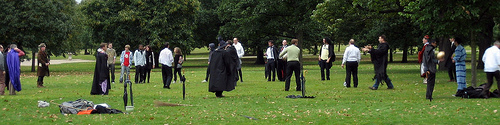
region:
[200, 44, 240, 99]
a person wearing a black cape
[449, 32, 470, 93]
a person wearing a blue strip jumpsuit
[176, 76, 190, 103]
an umbrellas stuck into th ground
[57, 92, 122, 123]
a pile of clothes on the grass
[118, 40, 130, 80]
a young man wearing a red t-shirt and gray jacket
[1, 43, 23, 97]
a person adjusting a blue cape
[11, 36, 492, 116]
people playing a mysterious game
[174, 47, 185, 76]
a girl carrying a bag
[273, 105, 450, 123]
brown leaves scattered on the ground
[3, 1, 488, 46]
trees surrounding the area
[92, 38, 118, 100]
person in long garmet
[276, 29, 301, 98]
man starting to swing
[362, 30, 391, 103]
man walking toward group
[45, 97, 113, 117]
heap of clothes on the ground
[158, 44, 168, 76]
person in white shirt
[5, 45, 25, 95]
bright blue garment on man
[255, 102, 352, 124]
flowers on the grass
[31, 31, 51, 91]
person standing watching men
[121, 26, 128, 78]
person in red shirt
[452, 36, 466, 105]
person in striped blue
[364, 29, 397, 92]
Man wearing a black shirt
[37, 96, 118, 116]
Pile of clothes on ground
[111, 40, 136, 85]
Man wearing a red shirt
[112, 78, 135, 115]
Umbrella sticking in the grass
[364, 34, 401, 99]
Man wearing blue jeans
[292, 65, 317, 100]
Umbrella sticking in dirt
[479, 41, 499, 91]
Man wearing a white shirt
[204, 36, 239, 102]
Man wearing a black robe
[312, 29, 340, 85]
Lady wearing black pants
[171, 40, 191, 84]
Lady wearing a black top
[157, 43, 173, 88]
man wearing a white shirt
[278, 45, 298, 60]
yellow shirt man is wearing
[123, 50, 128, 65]
red shirt boy is wearing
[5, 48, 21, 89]
purple cape person is wearing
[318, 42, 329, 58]
yellow top woman is wearing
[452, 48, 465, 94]
blue outfit person is wearing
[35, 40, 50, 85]
man wearing a black outfit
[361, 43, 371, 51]
red car in the distance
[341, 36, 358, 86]
man wearing a white shirt and black pants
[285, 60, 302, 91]
black pants man is wearing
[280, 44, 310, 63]
man wearing green shirt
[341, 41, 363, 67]
man wearing white shirt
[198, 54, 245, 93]
man wearing black robe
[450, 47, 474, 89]
man wearing blue outfit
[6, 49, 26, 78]
man wearing blue robe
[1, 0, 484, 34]
row of trees in the background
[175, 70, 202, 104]
umbrella in the ground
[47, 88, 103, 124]
pile of clothes in grass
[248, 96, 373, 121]
scattered leaves on grass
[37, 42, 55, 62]
man wearing hat on head